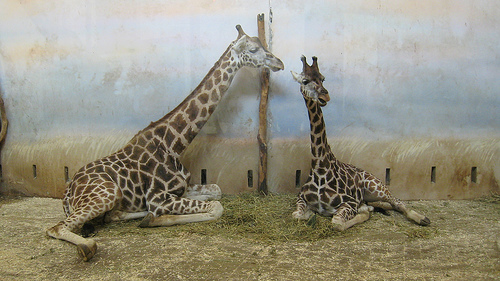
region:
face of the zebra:
[223, 16, 293, 93]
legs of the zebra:
[43, 215, 112, 274]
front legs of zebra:
[287, 195, 359, 237]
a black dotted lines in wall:
[17, 143, 491, 199]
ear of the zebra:
[240, 41, 267, 62]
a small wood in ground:
[242, 22, 294, 206]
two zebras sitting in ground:
[21, 23, 449, 253]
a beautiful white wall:
[11, 18, 494, 155]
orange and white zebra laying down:
[40, 4, 426, 279]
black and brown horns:
[295, 52, 327, 69]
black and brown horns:
[231, 26, 251, 36]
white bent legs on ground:
[158, 171, 220, 229]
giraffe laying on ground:
[276, 48, 441, 240]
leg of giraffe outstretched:
[38, 195, 102, 246]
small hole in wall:
[28, 159, 40, 178]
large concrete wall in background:
[36, 20, 121, 132]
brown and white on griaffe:
[315, 160, 347, 194]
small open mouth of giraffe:
[315, 79, 329, 111]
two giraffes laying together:
[38, 19, 423, 268]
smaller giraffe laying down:
[283, 52, 432, 234]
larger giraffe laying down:
[17, 24, 283, 264]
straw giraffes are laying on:
[84, 182, 414, 248]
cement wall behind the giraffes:
[2, 5, 494, 199]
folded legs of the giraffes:
[42, 177, 429, 259]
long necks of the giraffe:
[155, 66, 337, 164]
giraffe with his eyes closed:
[47, 24, 283, 255]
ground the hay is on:
[2, 190, 494, 279]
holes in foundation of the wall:
[26, 154, 489, 189]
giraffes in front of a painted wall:
[41, 23, 450, 260]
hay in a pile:
[184, 183, 349, 264]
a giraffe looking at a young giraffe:
[210, 25, 353, 122]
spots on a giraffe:
[119, 152, 166, 192]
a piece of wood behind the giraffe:
[251, 8, 284, 188]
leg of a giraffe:
[32, 205, 107, 265]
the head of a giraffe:
[229, 21, 289, 88]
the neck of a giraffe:
[167, 46, 234, 144]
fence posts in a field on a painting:
[381, 164, 490, 191]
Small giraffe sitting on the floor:
[290, 55, 433, 226]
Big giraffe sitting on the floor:
[45, 23, 285, 259]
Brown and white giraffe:
[53, 20, 285, 256]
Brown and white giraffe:
[286, 49, 437, 231]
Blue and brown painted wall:
[3, 0, 498, 192]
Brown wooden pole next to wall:
[250, 6, 273, 190]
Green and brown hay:
[113, 185, 410, 238]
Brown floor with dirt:
[4, 200, 496, 275]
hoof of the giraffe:
[71, 242, 99, 263]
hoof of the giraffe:
[411, 206, 433, 233]